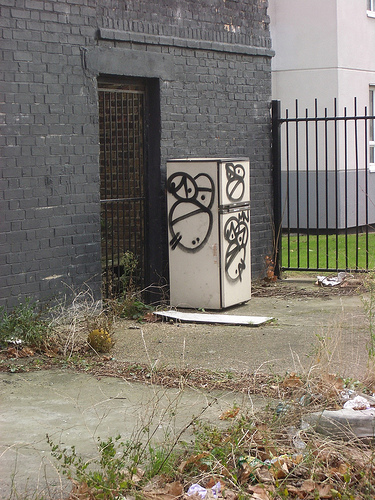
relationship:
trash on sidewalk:
[314, 383, 374, 429] [3, 270, 374, 497]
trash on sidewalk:
[306, 270, 357, 291] [3, 270, 374, 497]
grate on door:
[97, 82, 157, 318] [100, 73, 174, 317]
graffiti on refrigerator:
[167, 157, 250, 287] [161, 148, 259, 313]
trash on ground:
[314, 383, 374, 429] [1, 231, 373, 498]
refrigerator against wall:
[161, 148, 259, 313] [2, 2, 276, 344]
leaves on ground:
[4, 343, 373, 499] [1, 231, 373, 498]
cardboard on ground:
[145, 296, 279, 337] [1, 231, 373, 498]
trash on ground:
[306, 270, 357, 291] [1, 231, 373, 498]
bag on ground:
[302, 385, 375, 430] [1, 231, 373, 498]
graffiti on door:
[225, 205, 253, 285] [216, 203, 261, 312]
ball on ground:
[84, 318, 119, 356] [1, 231, 373, 498]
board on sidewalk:
[145, 296, 279, 337] [3, 270, 374, 497]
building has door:
[2, 2, 289, 342] [100, 73, 174, 317]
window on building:
[363, 80, 374, 175] [269, 1, 373, 244]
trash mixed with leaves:
[314, 383, 374, 429] [4, 343, 373, 499]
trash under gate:
[306, 270, 357, 291] [268, 91, 374, 286]